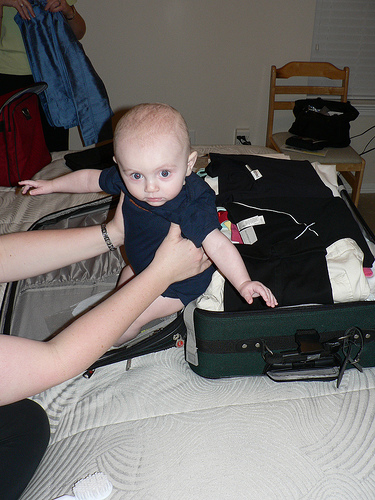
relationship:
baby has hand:
[16, 102, 279, 347] [239, 280, 278, 307]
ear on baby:
[107, 145, 126, 170] [17, 100, 278, 352]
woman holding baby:
[1, 191, 212, 406] [16, 102, 279, 347]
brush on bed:
[52, 471, 115, 498] [1, 185, 374, 498]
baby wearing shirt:
[16, 102, 279, 347] [98, 164, 221, 305]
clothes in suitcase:
[198, 151, 374, 311] [0, 151, 373, 386]